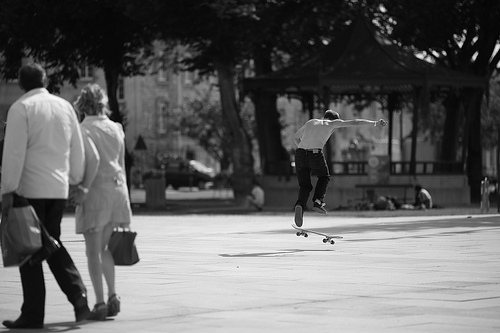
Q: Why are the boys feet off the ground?
A: Jumping.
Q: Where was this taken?
A: Park.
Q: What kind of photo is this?
A: Black and white.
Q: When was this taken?
A: Daytime.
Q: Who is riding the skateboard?
A: Boy.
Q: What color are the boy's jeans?
A: Black.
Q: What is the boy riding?
A: Skateboard.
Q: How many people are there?
A: 3.